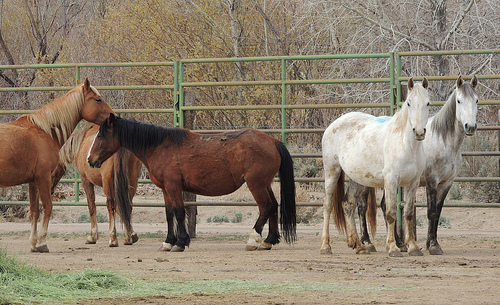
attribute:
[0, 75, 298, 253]
horses — brown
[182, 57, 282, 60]
pole — green, metal, fence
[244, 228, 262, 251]
hoof — white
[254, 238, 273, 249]
hoof — white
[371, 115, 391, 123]
mark — blue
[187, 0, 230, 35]
tree branch — dry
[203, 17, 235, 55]
tree branch — dry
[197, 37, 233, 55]
tree branch — dry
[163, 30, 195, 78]
tree branch — dry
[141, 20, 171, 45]
tree branch — dry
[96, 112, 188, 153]
mane — black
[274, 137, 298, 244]
tail — black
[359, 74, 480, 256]
horse — white, looking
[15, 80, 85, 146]
mane — yellow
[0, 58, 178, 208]
panel — green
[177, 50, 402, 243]
panel — green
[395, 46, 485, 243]
panel — green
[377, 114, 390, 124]
mark — blue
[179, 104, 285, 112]
pole — green, metal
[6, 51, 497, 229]
fence — metal, green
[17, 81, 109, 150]
mane — blond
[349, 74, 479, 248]
horse — standing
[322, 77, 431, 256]
horse — white, looking, standing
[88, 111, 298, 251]
horse — red, standing, brown, black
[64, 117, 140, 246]
horse — standing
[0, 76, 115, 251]
horse — red, standing, brown, tan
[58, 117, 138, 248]
horse — brown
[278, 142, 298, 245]
tail — black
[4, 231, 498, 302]
floor — sandy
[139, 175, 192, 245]
legs — HORSE'S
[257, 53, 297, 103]
pole — GREEN, METAL, FENCE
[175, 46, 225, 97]
pole — GREEN, METAL, FENCE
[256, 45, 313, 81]
pole — FENCE, METAL, GREEN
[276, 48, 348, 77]
pole — GREEN, METAL, FENCE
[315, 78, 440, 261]
horse — WHITE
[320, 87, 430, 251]
horse — WHITE, GREY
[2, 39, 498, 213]
fence — green, metal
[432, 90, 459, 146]
mane — grey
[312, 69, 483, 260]
horses — white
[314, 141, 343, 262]
leg — back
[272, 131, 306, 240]
tail — black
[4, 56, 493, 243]
fence — green